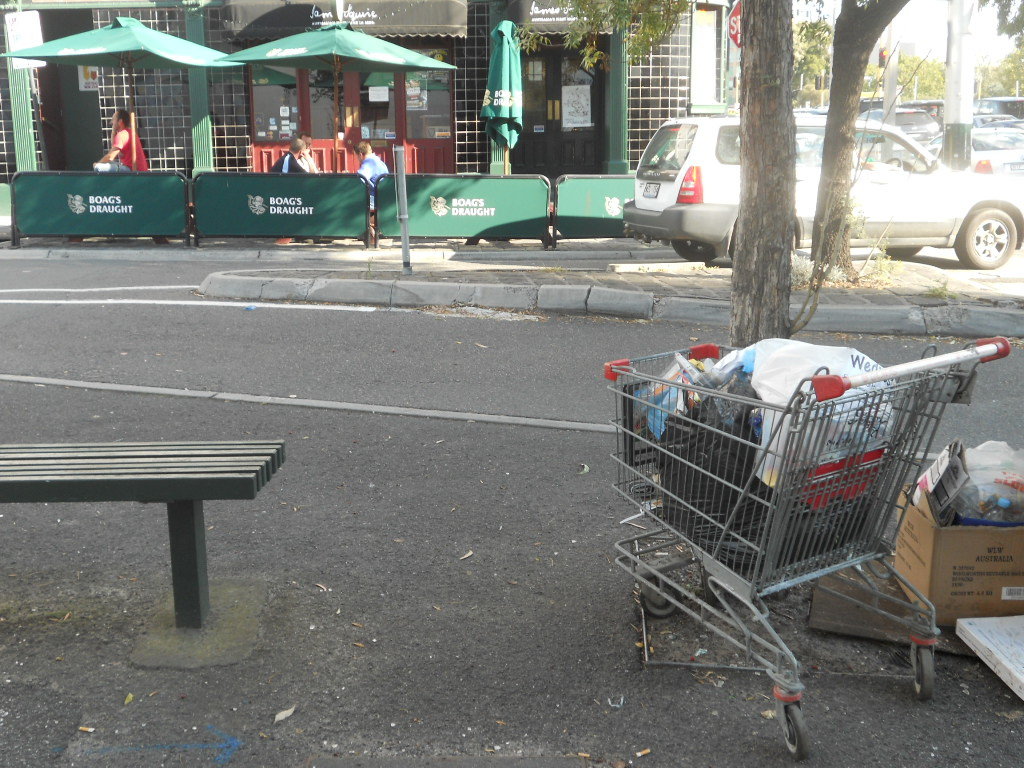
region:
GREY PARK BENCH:
[19, 418, 292, 644]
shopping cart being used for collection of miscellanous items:
[622, 333, 998, 740]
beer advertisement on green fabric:
[189, 169, 380, 250]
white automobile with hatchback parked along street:
[629, 108, 1013, 265]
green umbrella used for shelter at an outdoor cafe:
[240, 27, 450, 141]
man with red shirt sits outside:
[82, 84, 170, 182]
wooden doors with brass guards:
[500, 11, 624, 188]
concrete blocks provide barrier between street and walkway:
[314, 274, 666, 321]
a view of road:
[386, 541, 535, 750]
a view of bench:
[97, 385, 275, 559]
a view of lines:
[357, 360, 449, 443]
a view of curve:
[237, 206, 845, 394]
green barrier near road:
[76, 157, 640, 260]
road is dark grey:
[208, 281, 585, 421]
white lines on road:
[149, 279, 298, 450]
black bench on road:
[7, 413, 290, 626]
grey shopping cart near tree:
[537, 284, 953, 728]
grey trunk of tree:
[717, 1, 882, 352]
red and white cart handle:
[765, 328, 1021, 447]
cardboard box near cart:
[885, 449, 1009, 602]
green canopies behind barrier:
[37, 1, 445, 118]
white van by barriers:
[614, 92, 1008, 308]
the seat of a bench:
[26, 405, 283, 522]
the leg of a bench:
[140, 435, 254, 598]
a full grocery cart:
[558, 312, 947, 721]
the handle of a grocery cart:
[795, 318, 979, 414]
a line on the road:
[307, 373, 459, 446]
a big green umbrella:
[239, 13, 435, 91]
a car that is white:
[658, 101, 1000, 264]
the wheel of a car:
[965, 201, 1020, 271]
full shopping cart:
[593, 288, 1020, 703]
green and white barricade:
[23, 142, 192, 244]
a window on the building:
[649, 60, 695, 115]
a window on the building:
[617, 31, 643, 83]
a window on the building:
[462, 110, 485, 150]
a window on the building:
[447, 60, 473, 83]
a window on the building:
[193, 86, 233, 147]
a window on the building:
[146, 104, 169, 124]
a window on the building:
[157, 48, 174, 77]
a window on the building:
[90, 77, 113, 94]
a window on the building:
[160, 89, 174, 132]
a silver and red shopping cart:
[606, 336, 1012, 757]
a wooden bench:
[0, 443, 283, 637]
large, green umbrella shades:
[3, 20, 459, 179]